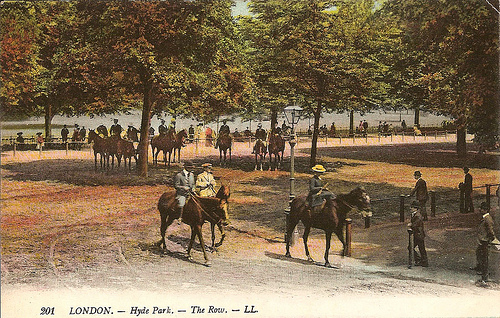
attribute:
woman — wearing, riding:
[162, 149, 234, 223]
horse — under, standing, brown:
[163, 203, 235, 249]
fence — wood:
[36, 130, 62, 141]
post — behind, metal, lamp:
[274, 97, 306, 172]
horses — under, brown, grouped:
[169, 197, 331, 250]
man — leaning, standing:
[403, 165, 456, 216]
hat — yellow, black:
[301, 164, 342, 202]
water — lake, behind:
[91, 106, 145, 116]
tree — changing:
[143, 23, 204, 72]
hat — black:
[174, 158, 202, 172]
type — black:
[289, 192, 342, 223]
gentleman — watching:
[97, 98, 178, 158]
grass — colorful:
[27, 169, 95, 233]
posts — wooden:
[424, 183, 444, 219]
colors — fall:
[42, 28, 95, 85]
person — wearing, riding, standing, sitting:
[167, 149, 205, 188]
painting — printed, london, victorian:
[27, 35, 367, 235]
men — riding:
[143, 154, 223, 192]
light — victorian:
[260, 99, 346, 195]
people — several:
[90, 117, 327, 191]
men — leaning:
[389, 168, 491, 203]